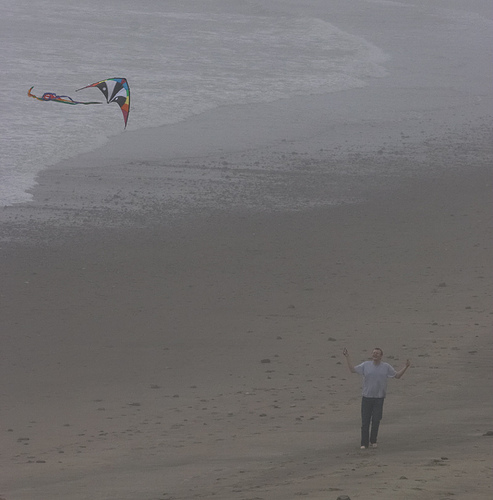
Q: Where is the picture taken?
A: On a beach.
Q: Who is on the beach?
A: A man.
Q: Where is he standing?
A: In the sand.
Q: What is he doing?
A: Flying a kite.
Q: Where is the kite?
A: In the air.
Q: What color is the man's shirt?
A: Gray.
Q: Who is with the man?
A: No one.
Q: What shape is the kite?
A: Arrow shaped.